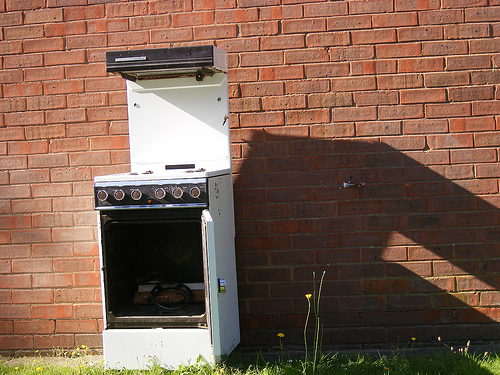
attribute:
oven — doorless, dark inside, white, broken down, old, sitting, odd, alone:
[93, 43, 246, 371]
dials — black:
[89, 175, 215, 206]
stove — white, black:
[93, 154, 224, 178]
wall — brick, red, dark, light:
[2, 3, 495, 350]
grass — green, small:
[3, 354, 499, 374]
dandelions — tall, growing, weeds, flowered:
[272, 265, 344, 369]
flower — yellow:
[7, 342, 100, 372]